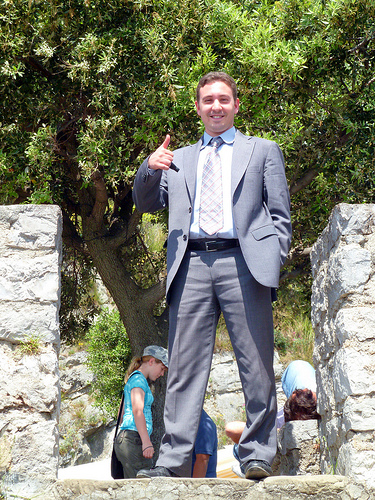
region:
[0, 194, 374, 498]
The man is standing on a rock wall.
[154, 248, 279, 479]
The man is wearing grey pants.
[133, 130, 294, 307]
The man has a grey jacket.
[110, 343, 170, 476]
A girl is leaning on a tree behind the man.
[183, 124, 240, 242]
The man is wearing a light blue shirt.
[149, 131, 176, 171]
The man is giving a thumbs up.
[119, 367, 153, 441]
The girl behind the man is wearing a blue shirt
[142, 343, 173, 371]
The girl behind the man is wearing a faded, camouflage hat.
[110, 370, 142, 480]
The girl is carrying a black purse.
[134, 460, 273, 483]
The man is wearing black shoes.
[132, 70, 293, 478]
man in suit is gesturing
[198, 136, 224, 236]
blue, red, and white tie on man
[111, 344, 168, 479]
girl stands behind man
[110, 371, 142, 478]
black purse worn by girl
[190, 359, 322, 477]
other people sitting behind man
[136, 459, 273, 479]
two black leather shoes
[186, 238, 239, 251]
black leather belt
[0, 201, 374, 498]
white rock wall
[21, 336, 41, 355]
small plant growing in brick wall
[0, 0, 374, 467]
green tree behind people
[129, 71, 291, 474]
a man wearing a suit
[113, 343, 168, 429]
a lady wearing a blue t-shirt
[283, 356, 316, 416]
a lady bending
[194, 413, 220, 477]
a man with a blue t-shirt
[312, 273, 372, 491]
a wall of stones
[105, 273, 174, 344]
the trunk of a tree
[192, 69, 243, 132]
a man with short hair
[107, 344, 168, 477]
a lady carrying a bag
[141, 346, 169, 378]
a lady wearing a cap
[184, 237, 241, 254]
Black belt worn by the man in a suit.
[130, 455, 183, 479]
Left black shoe of the man in the suit.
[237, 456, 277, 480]
Right black shoe worn by the man in a suit.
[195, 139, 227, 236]
Necktie worn by the man in a suit.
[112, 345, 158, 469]
Lady wearing a hat behind the man in a suit.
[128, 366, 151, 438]
Turquoise shirt worn by the lady in a hat.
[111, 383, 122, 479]
Black purse hanging from the shoulder of lady in a hat.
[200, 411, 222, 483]
Person in blue t-shirt behind the man wearing a suit.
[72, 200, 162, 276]
Black rope in the tree the lady with the hat is standing in front of.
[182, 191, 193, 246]
Buttons on the suit jacket the man is wearing.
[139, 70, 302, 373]
a man in a suit and tie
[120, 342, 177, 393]
a girl wearing a hat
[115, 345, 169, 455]
a girl wearing a blue shirt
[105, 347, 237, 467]
two people in blue shirts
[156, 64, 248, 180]
a man with the thumbs up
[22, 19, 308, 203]
green trees behind the man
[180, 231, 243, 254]
silver buckle on black belt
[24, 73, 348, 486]
a man standing between two stones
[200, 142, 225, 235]
a plaid pattern tie